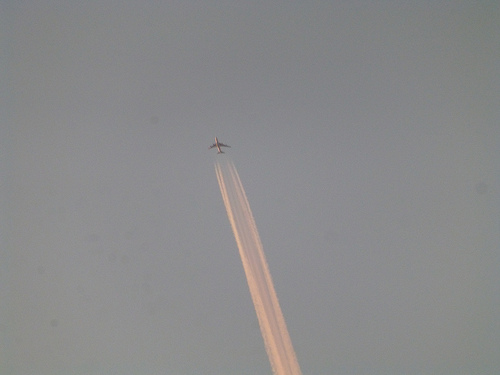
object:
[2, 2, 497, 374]
air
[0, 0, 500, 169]
gray sky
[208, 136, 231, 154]
airplane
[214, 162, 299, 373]
fumes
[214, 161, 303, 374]
streams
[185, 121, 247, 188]
grey plane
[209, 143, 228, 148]
engines